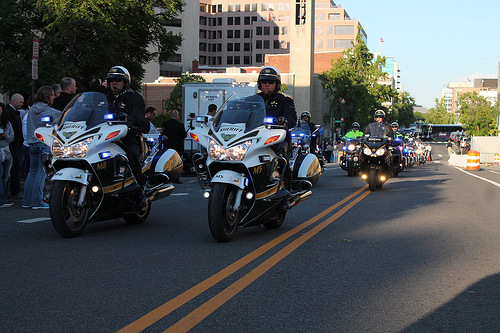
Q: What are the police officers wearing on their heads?
A: Helmets.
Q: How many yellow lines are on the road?
A: 2.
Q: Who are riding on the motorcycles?
A: Police officers.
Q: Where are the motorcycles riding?
A: On the road.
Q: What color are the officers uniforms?
A: Black.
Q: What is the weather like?
A: Sunny.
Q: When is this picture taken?
A: During the daytime.